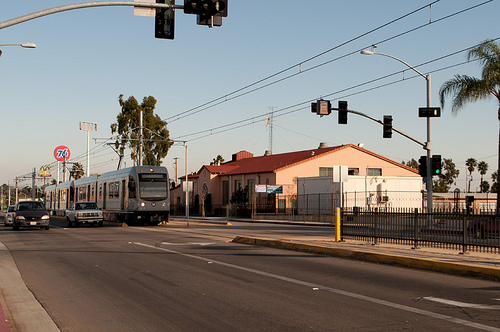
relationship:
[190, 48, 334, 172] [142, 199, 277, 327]
wires over street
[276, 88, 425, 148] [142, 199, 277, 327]
lights over street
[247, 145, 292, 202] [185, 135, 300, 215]
signs of businesses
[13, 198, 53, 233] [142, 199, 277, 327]
cars on street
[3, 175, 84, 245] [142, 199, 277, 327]
cars on street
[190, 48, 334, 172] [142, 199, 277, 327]
wires above street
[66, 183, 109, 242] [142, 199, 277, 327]
truck on street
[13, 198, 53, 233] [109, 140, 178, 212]
cars next to train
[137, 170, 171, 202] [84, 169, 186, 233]
shield on trolly